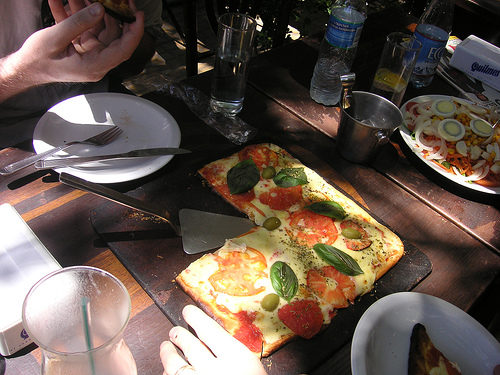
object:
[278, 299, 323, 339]
tomato slice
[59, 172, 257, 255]
pie server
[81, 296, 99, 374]
straw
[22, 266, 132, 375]
cup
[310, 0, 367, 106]
water bottle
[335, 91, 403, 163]
bucket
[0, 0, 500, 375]
table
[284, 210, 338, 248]
tomato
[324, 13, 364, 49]
label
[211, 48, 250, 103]
liquid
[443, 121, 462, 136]
yoke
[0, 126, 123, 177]
fork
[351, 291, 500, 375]
plate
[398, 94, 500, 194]
plate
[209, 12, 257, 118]
glass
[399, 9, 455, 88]
bottle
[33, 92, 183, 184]
plate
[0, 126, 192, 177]
utensil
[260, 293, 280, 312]
olive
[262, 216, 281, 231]
olive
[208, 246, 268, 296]
tomato slice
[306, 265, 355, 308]
tomato slice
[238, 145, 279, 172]
tomato slice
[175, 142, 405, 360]
pizza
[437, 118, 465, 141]
egg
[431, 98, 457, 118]
egg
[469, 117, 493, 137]
egg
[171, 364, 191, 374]
ring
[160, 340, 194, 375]
finger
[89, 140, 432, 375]
plate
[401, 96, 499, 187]
food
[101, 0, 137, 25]
food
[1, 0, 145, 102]
hand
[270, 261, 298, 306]
leaf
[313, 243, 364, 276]
leaf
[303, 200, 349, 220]
leaf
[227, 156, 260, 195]
leaf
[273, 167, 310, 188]
leaf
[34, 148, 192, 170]
butter knife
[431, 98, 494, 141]
eggs